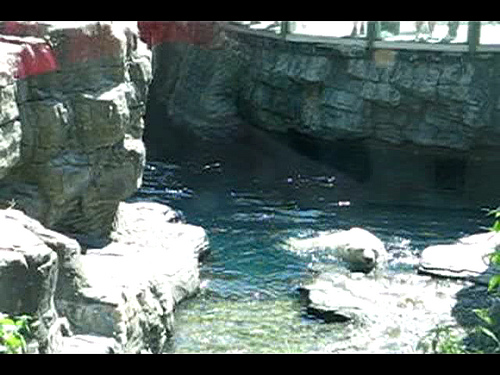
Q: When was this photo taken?
A: During the day.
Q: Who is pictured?
A: Nobody.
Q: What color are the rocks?
A: Grey.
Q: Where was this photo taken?
A: A zoo.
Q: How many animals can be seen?
A: Just 1.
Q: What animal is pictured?
A: A polar bear.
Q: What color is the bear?
A: White.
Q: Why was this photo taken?
A: To show the bear in its habitat.